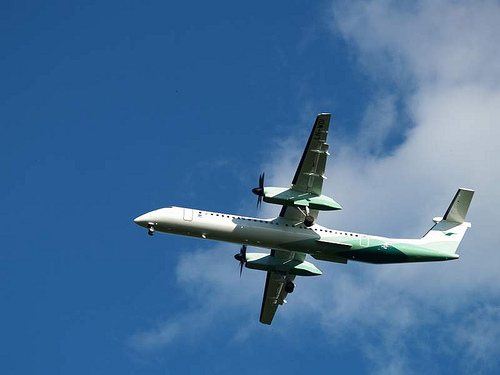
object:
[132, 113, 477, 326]
airplane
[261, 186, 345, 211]
engine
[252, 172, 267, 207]
propeller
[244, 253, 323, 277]
engine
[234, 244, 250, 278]
propeller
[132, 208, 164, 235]
nose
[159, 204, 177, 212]
cockpit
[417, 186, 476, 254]
tail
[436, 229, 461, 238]
logo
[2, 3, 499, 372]
sky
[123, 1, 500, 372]
clouds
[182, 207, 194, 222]
door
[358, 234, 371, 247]
door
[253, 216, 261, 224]
windows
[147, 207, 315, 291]
landing gear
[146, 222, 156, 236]
front landing gear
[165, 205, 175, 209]
window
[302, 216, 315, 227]
wheel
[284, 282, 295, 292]
wheel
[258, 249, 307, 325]
wing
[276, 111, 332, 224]
wing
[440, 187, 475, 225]
wing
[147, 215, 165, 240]
wheels